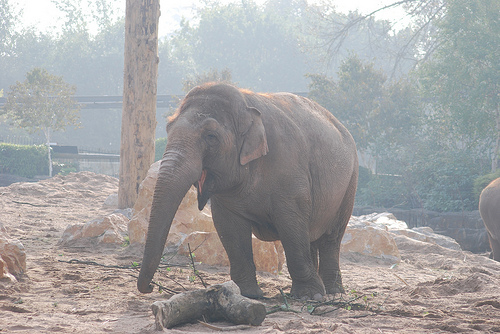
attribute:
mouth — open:
[195, 153, 207, 200]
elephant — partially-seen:
[480, 162, 496, 260]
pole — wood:
[118, 0, 160, 207]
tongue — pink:
[195, 162, 217, 196]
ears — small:
[237, 103, 282, 166]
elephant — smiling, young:
[136, 81, 358, 301]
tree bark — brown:
[96, 16, 189, 147]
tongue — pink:
[196, 174, 210, 194]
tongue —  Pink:
[193, 168, 210, 193]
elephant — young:
[57, 73, 359, 304]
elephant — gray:
[123, 75, 380, 305]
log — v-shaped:
[144, 274, 268, 324]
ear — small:
[239, 102, 272, 168]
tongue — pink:
[127, 145, 206, 296]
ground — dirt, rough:
[2, 172, 496, 329]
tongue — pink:
[197, 166, 207, 202]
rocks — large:
[357, 202, 424, 262]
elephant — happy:
[131, 58, 369, 298]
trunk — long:
[136, 149, 191, 274]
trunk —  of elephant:
[133, 147, 191, 294]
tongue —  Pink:
[196, 173, 202, 205]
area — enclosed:
[9, 166, 499, 332]